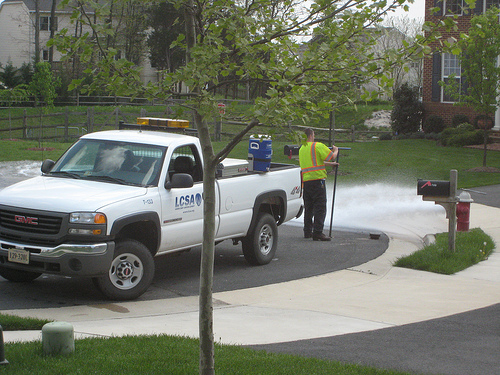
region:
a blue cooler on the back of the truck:
[236, 121, 279, 176]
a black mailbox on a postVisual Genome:
[400, 160, 465, 247]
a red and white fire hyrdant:
[450, 180, 475, 230]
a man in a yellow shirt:
[283, 120, 354, 237]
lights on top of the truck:
[128, 105, 198, 134]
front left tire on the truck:
[89, 232, 172, 314]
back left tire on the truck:
[238, 202, 293, 272]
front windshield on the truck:
[41, 126, 180, 189]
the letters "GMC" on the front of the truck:
[7, 207, 50, 234]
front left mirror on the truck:
[160, 167, 204, 196]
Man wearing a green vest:
[286, 118, 345, 246]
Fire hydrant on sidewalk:
[454, 188, 476, 236]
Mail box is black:
[410, 166, 465, 263]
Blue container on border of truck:
[243, 128, 277, 179]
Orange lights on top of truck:
[113, 111, 200, 136]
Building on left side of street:
[416, 1, 499, 146]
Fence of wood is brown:
[3, 106, 293, 145]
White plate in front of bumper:
[1, 240, 33, 270]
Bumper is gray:
[1, 244, 118, 286]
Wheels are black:
[103, 210, 284, 308]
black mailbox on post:
[418, 166, 457, 253]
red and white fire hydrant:
[456, 190, 474, 233]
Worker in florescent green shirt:
[301, 128, 338, 238]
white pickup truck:
[2, 105, 305, 301]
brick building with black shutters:
[423, 23, 498, 143]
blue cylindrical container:
[247, 134, 274, 171]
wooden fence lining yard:
[0, 104, 360, 156]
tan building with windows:
[0, 0, 190, 98]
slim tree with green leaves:
[113, 2, 300, 372]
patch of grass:
[2, 338, 382, 372]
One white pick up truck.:
[5, 111, 321, 273]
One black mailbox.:
[409, 158, 469, 255]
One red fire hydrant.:
[448, 176, 479, 232]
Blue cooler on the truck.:
[233, 120, 275, 177]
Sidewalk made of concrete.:
[1, 161, 492, 343]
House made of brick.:
[418, 0, 494, 154]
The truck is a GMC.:
[0, 210, 52, 231]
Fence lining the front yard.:
[0, 91, 370, 165]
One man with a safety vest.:
[289, 110, 344, 249]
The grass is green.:
[23, 87, 494, 196]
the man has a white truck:
[16, 119, 307, 288]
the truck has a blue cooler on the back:
[241, 127, 278, 179]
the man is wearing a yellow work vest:
[294, 135, 336, 185]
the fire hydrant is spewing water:
[338, 176, 485, 248]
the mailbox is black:
[413, 165, 464, 257]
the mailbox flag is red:
[417, 177, 434, 192]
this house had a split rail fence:
[92, 80, 458, 157]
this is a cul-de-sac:
[6, 110, 490, 325]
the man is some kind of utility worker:
[8, 38, 383, 309]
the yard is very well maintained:
[331, 64, 498, 199]